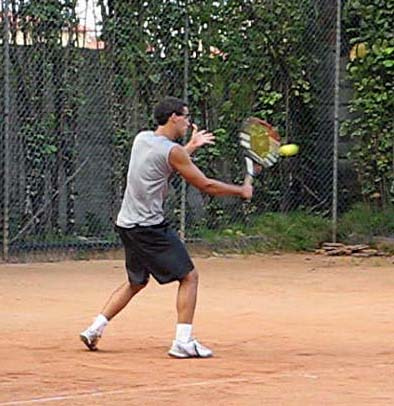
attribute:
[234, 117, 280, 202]
tennis racket — black and white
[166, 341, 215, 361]
tennis shoe — black and white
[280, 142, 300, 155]
tennis ball — yellow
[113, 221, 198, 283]
tennis shorts — black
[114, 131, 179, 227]
sleeveless shirt — grey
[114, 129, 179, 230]
grey shirt — sleeveless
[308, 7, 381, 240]
length fence — chain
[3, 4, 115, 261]
length fence — chain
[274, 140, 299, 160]
ball — yellow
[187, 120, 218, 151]
hand — wide open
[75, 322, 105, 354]
shoe — white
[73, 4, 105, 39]
sky — blue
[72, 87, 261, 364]
man — playing tennis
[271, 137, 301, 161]
tennis ball — yellow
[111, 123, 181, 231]
shirt — grey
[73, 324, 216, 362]
socks — white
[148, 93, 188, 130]
hair — black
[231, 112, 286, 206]
racket — black, white, red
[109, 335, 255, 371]
clay — red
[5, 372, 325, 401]
lines — white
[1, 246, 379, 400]
clay — red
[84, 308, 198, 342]
socks — white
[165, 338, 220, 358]
sneaker — white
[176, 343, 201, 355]
mark — black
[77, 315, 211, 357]
sneakers — white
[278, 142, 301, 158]
ball — yellow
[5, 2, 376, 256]
fence — long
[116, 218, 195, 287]
shorts — black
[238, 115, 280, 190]
racket — black, white, red